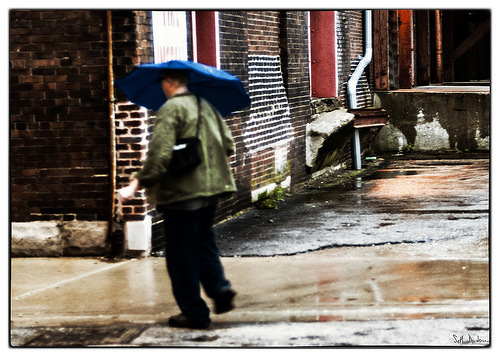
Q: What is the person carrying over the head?
A: Umbrella.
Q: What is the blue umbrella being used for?
A: To keep the rain off of the person.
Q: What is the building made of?
A: Red brick.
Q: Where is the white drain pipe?
A: On the side of the red brick building.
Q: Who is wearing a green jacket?
A: The man on the sidewalk.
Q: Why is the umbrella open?
A: Protect her head.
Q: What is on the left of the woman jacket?
A: Black purse.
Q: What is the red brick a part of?
A: A building.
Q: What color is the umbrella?
A: Blue.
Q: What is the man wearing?
A: A green jacket.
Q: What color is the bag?
A: Black.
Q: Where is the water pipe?
A: On the wall.